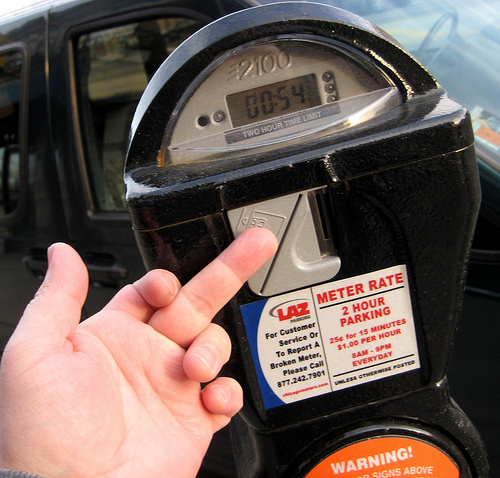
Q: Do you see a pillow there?
A: No, there are no pillows.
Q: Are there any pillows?
A: No, there are no pillows.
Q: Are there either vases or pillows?
A: No, there are no pillows or vases.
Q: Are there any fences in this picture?
A: No, there are no fences.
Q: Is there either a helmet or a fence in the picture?
A: No, there are no fences or helmets.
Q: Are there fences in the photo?
A: No, there are no fences.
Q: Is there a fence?
A: No, there are no fences.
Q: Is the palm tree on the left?
A: Yes, the palm tree is on the left of the image.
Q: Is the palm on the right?
A: No, the palm is on the left of the image.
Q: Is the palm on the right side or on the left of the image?
A: The palm is on the left of the image.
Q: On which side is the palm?
A: The palm is on the left of the image.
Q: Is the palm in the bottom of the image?
A: Yes, the palm is in the bottom of the image.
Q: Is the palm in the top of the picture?
A: No, the palm is in the bottom of the image.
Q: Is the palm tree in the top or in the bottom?
A: The palm tree is in the bottom of the image.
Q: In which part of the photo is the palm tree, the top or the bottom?
A: The palm tree is in the bottom of the image.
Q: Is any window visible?
A: Yes, there is a window.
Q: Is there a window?
A: Yes, there is a window.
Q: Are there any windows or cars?
A: Yes, there is a window.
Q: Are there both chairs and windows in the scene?
A: No, there is a window but no chairs.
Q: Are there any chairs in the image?
A: No, there are no chairs.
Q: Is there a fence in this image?
A: No, there are no fences.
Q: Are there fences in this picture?
A: No, there are no fences.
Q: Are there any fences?
A: No, there are no fences.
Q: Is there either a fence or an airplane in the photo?
A: No, there are no fences or airplanes.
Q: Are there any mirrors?
A: No, there are no mirrors.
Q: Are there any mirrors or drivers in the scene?
A: No, there are no mirrors or drivers.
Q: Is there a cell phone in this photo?
A: No, there are no cell phones.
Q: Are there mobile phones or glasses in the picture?
A: No, there are no mobile phones or glasses.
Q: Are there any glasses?
A: No, there are no glasses.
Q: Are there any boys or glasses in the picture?
A: No, there are no glasses or boys.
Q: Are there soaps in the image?
A: No, there are no soaps.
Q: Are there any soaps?
A: No, there are no soaps.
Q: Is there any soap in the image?
A: No, there are no soaps.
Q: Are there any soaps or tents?
A: No, there are no soaps or tents.